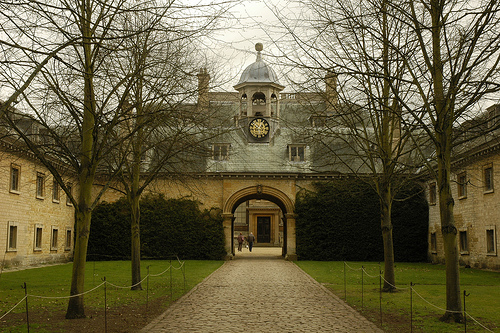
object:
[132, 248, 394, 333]
walkway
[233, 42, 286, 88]
roof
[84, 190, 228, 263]
ivy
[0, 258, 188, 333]
fence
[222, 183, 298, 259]
entryway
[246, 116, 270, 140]
clock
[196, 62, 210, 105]
chimney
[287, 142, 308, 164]
window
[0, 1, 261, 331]
tree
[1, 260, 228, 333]
grass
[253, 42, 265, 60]
cupola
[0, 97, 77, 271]
building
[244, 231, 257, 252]
person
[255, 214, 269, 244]
door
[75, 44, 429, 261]
building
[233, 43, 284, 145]
tower